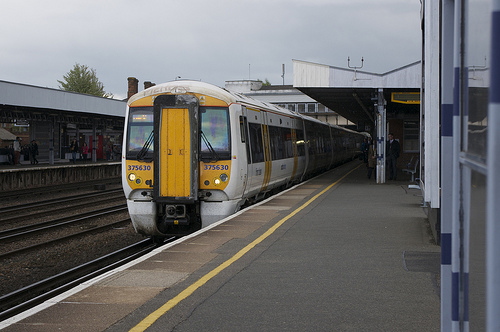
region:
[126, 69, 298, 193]
white and yellow passenger train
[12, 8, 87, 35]
white clouds in blue sky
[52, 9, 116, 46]
white clouds in blue sky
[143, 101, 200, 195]
yellow train door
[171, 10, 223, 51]
white clouds in blue sky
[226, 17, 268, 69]
white clouds in blue sky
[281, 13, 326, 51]
white clouds in blue sky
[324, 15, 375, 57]
white clouds in blue sky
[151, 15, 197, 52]
white clouds in blue sky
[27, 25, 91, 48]
white clouds in blue sky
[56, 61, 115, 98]
the top of the tree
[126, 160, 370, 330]
the yellow line on the walkway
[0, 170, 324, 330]
the white line on the walkway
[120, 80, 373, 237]
the train on the track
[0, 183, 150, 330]
the tracks on the ground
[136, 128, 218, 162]
the wipers on the train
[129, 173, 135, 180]
the light on the train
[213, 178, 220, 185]
the light on the train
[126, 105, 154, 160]
the window on the train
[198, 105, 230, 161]
the window on the train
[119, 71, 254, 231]
train the railway station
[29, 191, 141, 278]
track in front of the train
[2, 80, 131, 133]
shed in the railway station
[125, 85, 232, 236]
front of the train with yellow color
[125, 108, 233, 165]
front glass with wiper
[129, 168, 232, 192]
head light in front of the train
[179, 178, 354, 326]
platform at the railway station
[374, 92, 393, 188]
piller of the shed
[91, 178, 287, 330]
platfrom marked in white and yellow color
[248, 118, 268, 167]
window of the train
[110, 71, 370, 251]
A train in the foreground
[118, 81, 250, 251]
The back view of a train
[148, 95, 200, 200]
A yellow colored door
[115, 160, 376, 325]
A long yellow line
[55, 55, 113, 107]
A Tall tree in the background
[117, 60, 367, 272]
Train is on the train tracks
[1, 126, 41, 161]
People are in the background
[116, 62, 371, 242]
Train is white and yellow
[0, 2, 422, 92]
The sky is cloudy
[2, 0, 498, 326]
Photo was taken outdoors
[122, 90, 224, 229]
The front of the train is yellow.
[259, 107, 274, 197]
The doors on the side of the train are yellow.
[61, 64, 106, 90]
The tree leaves in the background are green.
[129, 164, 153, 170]
The numbers on the front of the train is blue.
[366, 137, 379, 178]
The woman is wearing a brown coat.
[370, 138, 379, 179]
The woman is wearing black pants.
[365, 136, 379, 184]
The woman is wearing a white shirt.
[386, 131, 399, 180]
The man is wearing a black jacket.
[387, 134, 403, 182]
The man is wearing dark pants.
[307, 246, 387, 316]
The pavement is gray.